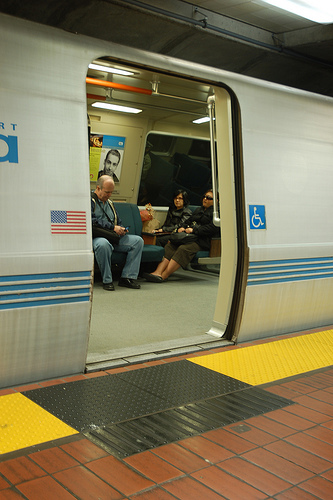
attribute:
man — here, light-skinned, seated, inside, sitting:
[91, 175, 143, 291]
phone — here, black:
[121, 225, 129, 237]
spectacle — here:
[96, 186, 114, 197]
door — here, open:
[85, 56, 247, 372]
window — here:
[138, 134, 216, 207]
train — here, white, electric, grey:
[1, 9, 333, 388]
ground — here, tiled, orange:
[0, 323, 332, 500]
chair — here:
[113, 201, 165, 263]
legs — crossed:
[149, 229, 195, 281]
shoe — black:
[122, 279, 139, 288]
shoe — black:
[104, 281, 117, 290]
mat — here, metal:
[22, 357, 296, 461]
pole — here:
[207, 95, 223, 227]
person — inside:
[150, 193, 218, 280]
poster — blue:
[89, 132, 126, 188]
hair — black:
[165, 190, 188, 211]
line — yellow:
[0, 393, 80, 456]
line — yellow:
[187, 327, 331, 387]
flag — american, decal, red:
[52, 211, 89, 234]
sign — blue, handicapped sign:
[250, 203, 268, 230]